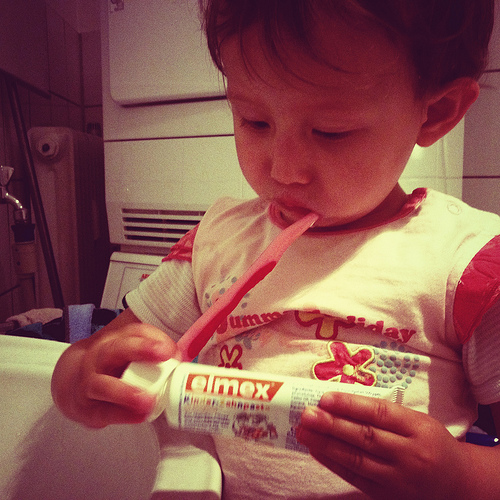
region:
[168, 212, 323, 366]
toothbrush in toddler's mouth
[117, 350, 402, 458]
toddler holding toothpast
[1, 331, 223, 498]
toddler standing next to sink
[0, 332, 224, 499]
sink is white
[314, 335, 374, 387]
flower on toddlers shirt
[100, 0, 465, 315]
washer-dryer behind the toddler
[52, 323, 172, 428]
top of toothpaste tube in toddler's hand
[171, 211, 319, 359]
toddler's toothbrush is pink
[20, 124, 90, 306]
radiator next to the washer-dryer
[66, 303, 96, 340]
blue cloth behind toddler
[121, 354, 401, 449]
white orange toothpaste with text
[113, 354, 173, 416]
rounded white toothpaste cap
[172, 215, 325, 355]
dark pink and light pink toothbrush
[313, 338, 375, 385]
yellow and pink flower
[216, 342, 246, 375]
yellow and pink flower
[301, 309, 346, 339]
yellow and pink flower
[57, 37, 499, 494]
brown haired toddler brushing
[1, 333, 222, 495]
white edge of sink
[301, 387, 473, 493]
small child hand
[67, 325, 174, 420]
small child hand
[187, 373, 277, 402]
Elmex written in white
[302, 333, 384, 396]
Red and yellow flower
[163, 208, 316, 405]
Pink and red tooth brush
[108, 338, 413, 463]
Hands holding a tube of tooth paste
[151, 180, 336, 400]
A tooth brush in a mouth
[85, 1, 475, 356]
A washing machine in the background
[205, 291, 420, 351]
Writing on a t-shirt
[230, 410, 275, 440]
A drawing on the tube of toothpaste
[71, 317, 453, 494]
A pair of child's hands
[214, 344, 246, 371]
A yellow flower with a red boarder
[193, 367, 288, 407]
elmex written on paste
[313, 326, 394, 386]
flower on babys shirt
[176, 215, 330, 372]
it is a pink tooth brush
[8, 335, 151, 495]
the sink is white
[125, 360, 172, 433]
the top of paste is open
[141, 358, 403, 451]
the bottle is white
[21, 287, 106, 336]
the clothing is blue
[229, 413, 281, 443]
drawing on paste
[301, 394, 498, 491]
babys hand are brown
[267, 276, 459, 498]
babys shirt is white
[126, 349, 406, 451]
a tube of toothpaste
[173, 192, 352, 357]
A toothbrush sticking out of a mouth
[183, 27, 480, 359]
A child with a toothbrush sticking out of their mouth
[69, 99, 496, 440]
A child holding a tube of toothpaste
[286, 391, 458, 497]
a hand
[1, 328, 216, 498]
a sink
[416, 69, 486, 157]
an ear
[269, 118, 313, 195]
a nose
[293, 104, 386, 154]
an eye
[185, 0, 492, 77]
hair and a forehead